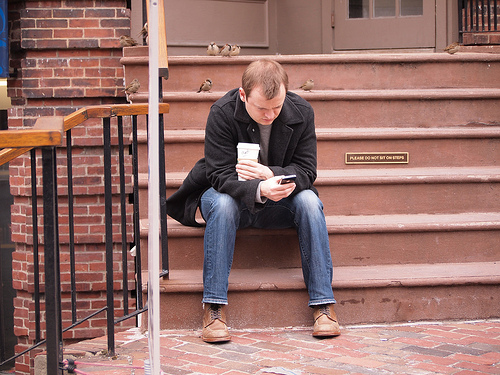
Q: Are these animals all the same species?
A: Yes, all the animals are birds.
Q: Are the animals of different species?
A: No, all the animals are birds.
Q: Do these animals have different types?
A: No, all the animals are birds.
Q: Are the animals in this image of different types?
A: No, all the animals are birds.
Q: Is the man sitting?
A: Yes, the man is sitting.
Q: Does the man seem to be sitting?
A: Yes, the man is sitting.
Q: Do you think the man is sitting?
A: Yes, the man is sitting.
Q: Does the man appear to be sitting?
A: Yes, the man is sitting.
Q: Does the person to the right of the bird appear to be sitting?
A: Yes, the man is sitting.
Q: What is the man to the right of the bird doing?
A: The man is sitting.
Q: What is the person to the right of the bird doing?
A: The man is sitting.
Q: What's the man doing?
A: The man is sitting.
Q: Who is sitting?
A: The man is sitting.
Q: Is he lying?
A: No, the man is sitting.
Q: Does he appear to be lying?
A: No, the man is sitting.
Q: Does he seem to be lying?
A: No, the man is sitting.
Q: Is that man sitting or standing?
A: The man is sitting.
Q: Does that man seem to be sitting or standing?
A: The man is sitting.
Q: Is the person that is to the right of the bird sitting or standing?
A: The man is sitting.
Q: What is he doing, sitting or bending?
A: The man is sitting.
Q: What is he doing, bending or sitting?
A: The man is sitting.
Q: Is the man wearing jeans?
A: Yes, the man is wearing jeans.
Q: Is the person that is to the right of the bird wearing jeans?
A: Yes, the man is wearing jeans.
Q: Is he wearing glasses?
A: No, the man is wearing jeans.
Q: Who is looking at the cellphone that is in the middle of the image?
A: The man is looking at the mobile phone.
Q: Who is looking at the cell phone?
A: The man is looking at the mobile phone.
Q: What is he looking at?
A: The man is looking at the cellphone.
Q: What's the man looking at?
A: The man is looking at the cellphone.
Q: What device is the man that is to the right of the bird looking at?
A: The man is looking at the cell phone.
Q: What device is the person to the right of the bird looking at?
A: The man is looking at the cell phone.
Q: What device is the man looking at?
A: The man is looking at the cell phone.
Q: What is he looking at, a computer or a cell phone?
A: The man is looking at a cell phone.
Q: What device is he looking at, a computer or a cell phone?
A: The man is looking at a cell phone.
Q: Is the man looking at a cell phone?
A: Yes, the man is looking at a cell phone.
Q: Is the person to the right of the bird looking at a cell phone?
A: Yes, the man is looking at a cell phone.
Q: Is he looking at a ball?
A: No, the man is looking at a cell phone.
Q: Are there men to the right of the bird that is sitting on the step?
A: Yes, there is a man to the right of the bird.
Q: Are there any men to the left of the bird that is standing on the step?
A: No, the man is to the right of the bird.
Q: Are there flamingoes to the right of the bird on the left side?
A: No, there is a man to the right of the bird.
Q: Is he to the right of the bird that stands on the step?
A: Yes, the man is to the right of the bird.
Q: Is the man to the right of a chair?
A: No, the man is to the right of the bird.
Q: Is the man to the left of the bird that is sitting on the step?
A: No, the man is to the right of the bird.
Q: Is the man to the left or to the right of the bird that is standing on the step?
A: The man is to the right of the bird.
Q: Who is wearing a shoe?
A: The man is wearing a shoe.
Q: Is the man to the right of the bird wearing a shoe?
A: Yes, the man is wearing a shoe.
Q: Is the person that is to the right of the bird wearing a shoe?
A: Yes, the man is wearing a shoe.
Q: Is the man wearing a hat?
A: No, the man is wearing a shoe.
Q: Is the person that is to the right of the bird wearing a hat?
A: No, the man is wearing a shoe.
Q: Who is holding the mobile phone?
A: The man is holding the mobile phone.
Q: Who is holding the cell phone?
A: The man is holding the mobile phone.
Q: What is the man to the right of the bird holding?
A: The man is holding the mobile phone.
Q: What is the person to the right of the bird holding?
A: The man is holding the mobile phone.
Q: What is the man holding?
A: The man is holding the mobile phone.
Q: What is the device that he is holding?
A: The device is a cell phone.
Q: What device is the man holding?
A: The man is holding the mobile phone.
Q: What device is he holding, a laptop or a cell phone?
A: The man is holding a cell phone.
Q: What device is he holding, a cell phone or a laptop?
A: The man is holding a cell phone.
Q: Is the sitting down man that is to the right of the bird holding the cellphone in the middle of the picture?
A: Yes, the man is holding the cell phone.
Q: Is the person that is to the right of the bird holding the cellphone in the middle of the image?
A: Yes, the man is holding the cell phone.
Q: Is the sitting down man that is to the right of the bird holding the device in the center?
A: Yes, the man is holding the cell phone.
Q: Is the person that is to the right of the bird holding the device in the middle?
A: Yes, the man is holding the cell phone.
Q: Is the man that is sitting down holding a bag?
A: No, the man is holding the cell phone.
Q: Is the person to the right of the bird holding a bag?
A: No, the man is holding the cell phone.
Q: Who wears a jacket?
A: The man wears a jacket.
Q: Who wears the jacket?
A: The man wears a jacket.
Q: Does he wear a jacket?
A: Yes, the man wears a jacket.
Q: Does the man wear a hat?
A: No, the man wears a jacket.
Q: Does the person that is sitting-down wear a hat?
A: No, the man wears a jacket.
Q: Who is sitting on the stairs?
A: The man is sitting on the stairs.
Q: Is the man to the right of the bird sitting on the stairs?
A: Yes, the man is sitting on the stairs.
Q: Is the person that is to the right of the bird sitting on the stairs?
A: Yes, the man is sitting on the stairs.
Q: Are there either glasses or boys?
A: No, there are no boys or glasses.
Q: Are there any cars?
A: No, there are no cars.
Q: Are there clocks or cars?
A: No, there are no cars or clocks.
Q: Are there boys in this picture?
A: No, there are no boys.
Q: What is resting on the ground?
A: The shoe is resting on the ground.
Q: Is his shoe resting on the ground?
A: Yes, the shoe is resting on the ground.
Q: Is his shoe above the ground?
A: Yes, the shoe is above the ground.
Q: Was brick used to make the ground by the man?
A: Yes, the ground is made of brick.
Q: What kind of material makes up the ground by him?
A: The ground is made of brick.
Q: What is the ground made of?
A: The ground is made of brick.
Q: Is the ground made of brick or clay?
A: The ground is made of brick.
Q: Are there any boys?
A: No, there are no boys.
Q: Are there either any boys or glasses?
A: No, there are no boys or glasses.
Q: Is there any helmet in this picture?
A: No, there are no helmets.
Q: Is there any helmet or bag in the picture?
A: No, there are no helmets or bags.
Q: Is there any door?
A: Yes, there is a door.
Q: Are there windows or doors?
A: Yes, there is a door.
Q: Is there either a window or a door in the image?
A: Yes, there is a door.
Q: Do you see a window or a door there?
A: Yes, there is a door.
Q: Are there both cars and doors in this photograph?
A: No, there is a door but no cars.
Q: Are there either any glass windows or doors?
A: Yes, there is a glass door.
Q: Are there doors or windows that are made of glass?
A: Yes, the door is made of glass.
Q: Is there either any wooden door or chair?
A: Yes, there is a wood door.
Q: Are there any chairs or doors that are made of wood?
A: Yes, the door is made of wood.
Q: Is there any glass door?
A: Yes, there is a door that is made of glass.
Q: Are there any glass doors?
A: Yes, there is a door that is made of glass.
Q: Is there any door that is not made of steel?
A: Yes, there is a door that is made of glass.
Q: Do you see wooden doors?
A: Yes, there is a wood door.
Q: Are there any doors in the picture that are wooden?
A: Yes, there is a door that is wooden.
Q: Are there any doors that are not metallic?
A: Yes, there is a wooden door.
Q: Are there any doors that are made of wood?
A: Yes, there is a door that is made of wood.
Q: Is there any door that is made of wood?
A: Yes, there is a door that is made of wood.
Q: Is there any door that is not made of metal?
A: Yes, there is a door that is made of wood.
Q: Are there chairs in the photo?
A: No, there are no chairs.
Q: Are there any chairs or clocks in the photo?
A: No, there are no chairs or clocks.